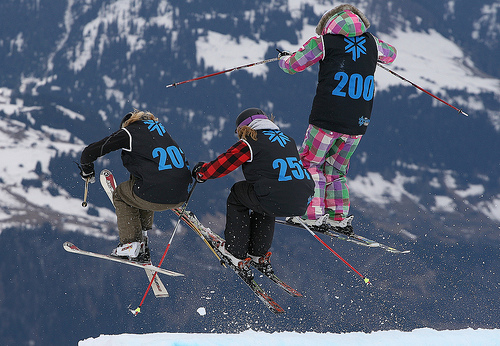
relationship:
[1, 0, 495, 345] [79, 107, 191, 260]
mountain in front of person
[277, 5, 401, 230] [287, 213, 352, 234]
person wearing ski boots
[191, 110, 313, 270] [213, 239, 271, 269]
person wearing ski boots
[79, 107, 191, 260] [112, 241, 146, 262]
person wearing ski boots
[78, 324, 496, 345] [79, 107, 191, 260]
snow below person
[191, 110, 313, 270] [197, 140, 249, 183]
person in plaid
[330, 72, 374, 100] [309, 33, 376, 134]
200 on vest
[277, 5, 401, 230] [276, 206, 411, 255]
person wearing skis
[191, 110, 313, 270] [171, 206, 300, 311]
person wearing skis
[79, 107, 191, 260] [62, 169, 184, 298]
person wearing skis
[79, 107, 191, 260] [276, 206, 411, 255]
person wearing skis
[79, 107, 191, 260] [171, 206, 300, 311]
person wearing skis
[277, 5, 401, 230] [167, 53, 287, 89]
person holding pole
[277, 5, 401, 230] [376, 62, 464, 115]
person holding pole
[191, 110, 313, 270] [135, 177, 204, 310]
person holding pole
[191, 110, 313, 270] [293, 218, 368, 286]
person holding pole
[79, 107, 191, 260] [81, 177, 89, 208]
person holding pole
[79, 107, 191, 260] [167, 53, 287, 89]
person holding pole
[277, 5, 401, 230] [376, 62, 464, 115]
person has pole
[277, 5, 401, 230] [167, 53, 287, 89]
person has pole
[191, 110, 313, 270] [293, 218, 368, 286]
person has pole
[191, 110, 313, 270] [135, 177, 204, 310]
person has pole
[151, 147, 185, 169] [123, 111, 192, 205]
202 on vest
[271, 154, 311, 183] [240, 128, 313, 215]
251 on vest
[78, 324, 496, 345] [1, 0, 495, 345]
snow on mountain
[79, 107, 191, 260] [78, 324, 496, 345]
person above snow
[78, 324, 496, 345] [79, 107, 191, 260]
snow beneath person